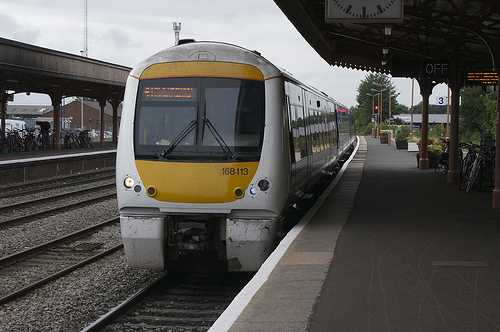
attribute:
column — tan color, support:
[403, 75, 444, 158]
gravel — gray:
[0, 177, 157, 330]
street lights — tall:
[352, 79, 400, 149]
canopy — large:
[0, 36, 135, 106]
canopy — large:
[273, 0, 498, 82]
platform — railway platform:
[203, 135, 497, 330]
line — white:
[204, 127, 362, 329]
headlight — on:
[121, 172, 138, 193]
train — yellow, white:
[115, 40, 356, 271]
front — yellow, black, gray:
[113, 33, 287, 265]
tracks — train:
[2, 176, 125, 325]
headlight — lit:
[119, 175, 137, 191]